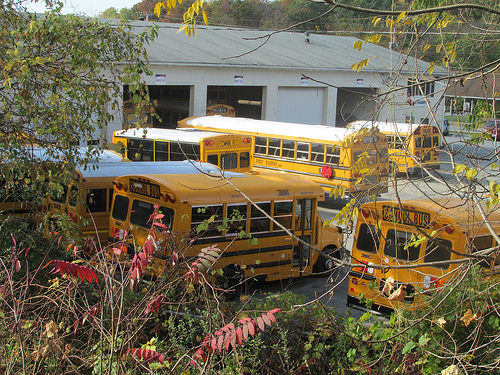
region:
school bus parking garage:
[41, 91, 496, 331]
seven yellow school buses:
[6, 85, 498, 316]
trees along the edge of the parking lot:
[8, 9, 496, 374]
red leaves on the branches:
[33, 202, 276, 365]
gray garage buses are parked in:
[3, 12, 445, 147]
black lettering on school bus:
[378, 201, 428, 225]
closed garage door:
[280, 85, 323, 132]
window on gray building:
[403, 81, 435, 98]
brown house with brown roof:
[444, 63, 496, 123]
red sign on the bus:
[318, 163, 333, 179]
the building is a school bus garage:
[3, 8, 461, 180]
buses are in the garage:
[121, 73, 266, 135]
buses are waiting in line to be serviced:
[121, 115, 446, 188]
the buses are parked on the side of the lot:
[6, 123, 499, 320]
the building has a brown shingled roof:
[445, 65, 499, 127]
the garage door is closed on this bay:
[266, 76, 330, 146]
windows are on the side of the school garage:
[390, 75, 444, 145]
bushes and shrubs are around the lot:
[6, 7, 498, 374]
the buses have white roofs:
[116, 112, 451, 160]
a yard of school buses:
[30, 77, 495, 320]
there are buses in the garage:
[128, 80, 263, 132]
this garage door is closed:
[267, 76, 347, 142]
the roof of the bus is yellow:
[191, 105, 386, 157]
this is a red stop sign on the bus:
[307, 161, 351, 191]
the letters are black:
[371, 198, 446, 230]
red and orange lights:
[198, 135, 220, 149]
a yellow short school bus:
[112, 168, 344, 288]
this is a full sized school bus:
[187, 105, 400, 193]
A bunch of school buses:
[83, 65, 486, 296]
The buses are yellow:
[82, 103, 474, 295]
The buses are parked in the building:
[122, 80, 256, 118]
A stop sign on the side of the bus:
[311, 161, 341, 173]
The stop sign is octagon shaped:
[313, 160, 341, 178]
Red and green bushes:
[8, 223, 368, 374]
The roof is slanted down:
[134, 10, 295, 67]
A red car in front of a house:
[476, 105, 498, 147]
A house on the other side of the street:
[451, 72, 499, 115]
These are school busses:
[5, 106, 495, 308]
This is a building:
[10, 6, 448, 169]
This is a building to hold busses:
[8, 4, 463, 163]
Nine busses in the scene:
[35, 83, 482, 328]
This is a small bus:
[104, 115, 259, 181]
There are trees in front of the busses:
[9, 230, 494, 372]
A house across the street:
[430, 65, 498, 140]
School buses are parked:
[0, 100, 499, 336]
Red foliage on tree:
[56, 206, 263, 373]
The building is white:
[14, 0, 443, 160]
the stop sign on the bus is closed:
[321, 163, 333, 178]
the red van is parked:
[482, 115, 499, 139]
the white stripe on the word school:
[133, 181, 146, 190]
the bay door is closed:
[277, 86, 327, 128]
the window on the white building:
[407, 75, 436, 98]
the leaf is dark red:
[43, 258, 102, 288]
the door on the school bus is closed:
[292, 199, 313, 278]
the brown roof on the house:
[446, 69, 499, 101]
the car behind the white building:
[441, 113, 451, 139]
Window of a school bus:
[356, 220, 380, 256]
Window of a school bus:
[382, 231, 419, 263]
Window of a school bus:
[425, 237, 451, 267]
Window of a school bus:
[193, 203, 223, 235]